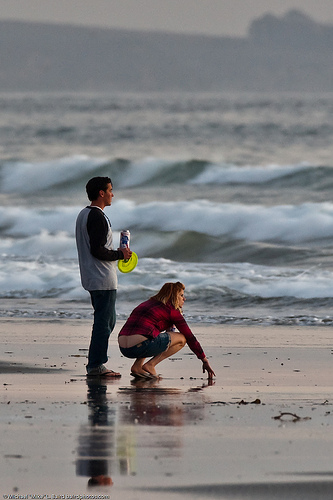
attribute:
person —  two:
[117, 282, 216, 382]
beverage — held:
[120, 226, 129, 249]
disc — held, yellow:
[109, 251, 143, 275]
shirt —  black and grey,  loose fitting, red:
[74, 205, 122, 291]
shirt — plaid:
[117, 292, 205, 358]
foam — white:
[197, 258, 326, 301]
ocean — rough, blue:
[0, 89, 329, 325]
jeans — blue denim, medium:
[73, 278, 130, 376]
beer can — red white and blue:
[121, 227, 130, 248]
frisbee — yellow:
[117, 248, 137, 273]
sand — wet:
[1, 294, 329, 498]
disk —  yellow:
[116, 249, 139, 274]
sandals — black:
[82, 366, 121, 379]